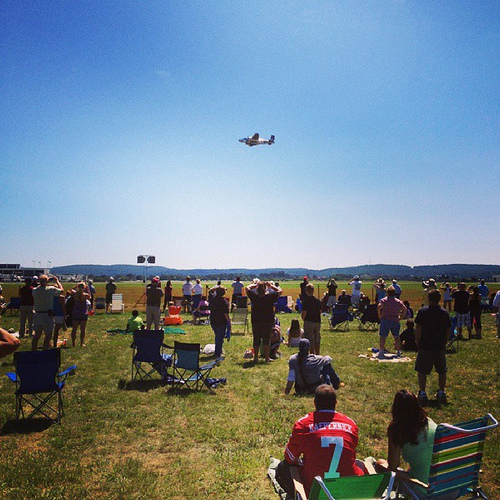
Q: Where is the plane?
A: On the sky.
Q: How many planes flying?
A: One.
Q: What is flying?
A: A plane.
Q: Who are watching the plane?
A: People.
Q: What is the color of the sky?
A: Blue.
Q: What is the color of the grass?
A: Green.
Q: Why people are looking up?
A: To watch the plane.